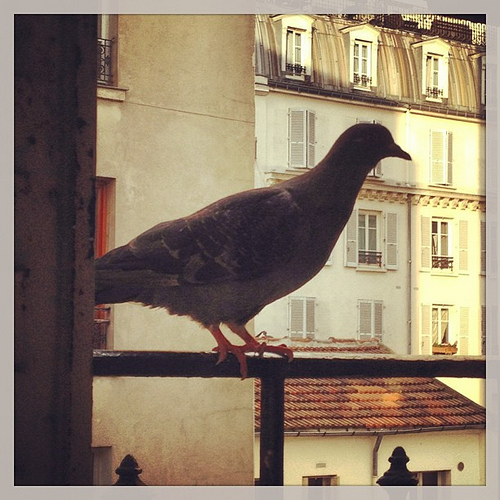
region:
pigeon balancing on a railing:
[83, 117, 421, 390]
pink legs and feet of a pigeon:
[201, 317, 297, 382]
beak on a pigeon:
[390, 144, 418, 166]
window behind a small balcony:
[423, 216, 458, 274]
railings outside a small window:
[347, 70, 382, 93]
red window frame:
[86, 174, 121, 324]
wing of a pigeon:
[104, 185, 314, 291]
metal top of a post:
[372, 442, 419, 485]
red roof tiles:
[252, 374, 484, 441]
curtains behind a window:
[429, 308, 451, 345]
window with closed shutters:
[283, 96, 323, 173]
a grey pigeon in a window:
[104, 112, 412, 337]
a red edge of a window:
[93, 185, 123, 357]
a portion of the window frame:
[17, 19, 129, 499]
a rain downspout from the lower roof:
[364, 430, 394, 496]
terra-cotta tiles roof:
[296, 372, 483, 446]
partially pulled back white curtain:
[425, 281, 467, 352]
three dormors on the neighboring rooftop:
[270, 10, 452, 105]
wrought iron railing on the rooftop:
[371, 17, 493, 51]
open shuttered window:
[332, 191, 407, 278]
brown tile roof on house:
[288, 386, 326, 419]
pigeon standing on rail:
[85, 106, 417, 383]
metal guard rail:
[259, 360, 285, 490]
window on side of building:
[279, 15, 319, 74]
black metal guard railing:
[95, 36, 112, 86]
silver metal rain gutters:
[342, 427, 410, 439]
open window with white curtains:
[425, 293, 462, 360]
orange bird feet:
[198, 319, 299, 379]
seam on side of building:
[128, 92, 253, 127]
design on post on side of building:
[374, 444, 421, 495]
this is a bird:
[85, 110, 411, 360]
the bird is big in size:
[93, 118, 423, 360]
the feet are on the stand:
[191, 330, 298, 374]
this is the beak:
[392, 147, 414, 164]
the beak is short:
[389, 150, 416, 160]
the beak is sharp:
[392, 146, 414, 164]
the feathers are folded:
[179, 217, 262, 274]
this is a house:
[373, 194, 477, 310]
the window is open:
[352, 217, 394, 254]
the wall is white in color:
[448, 285, 467, 300]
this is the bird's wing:
[156, 230, 287, 274]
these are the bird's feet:
[208, 324, 308, 378]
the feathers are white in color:
[201, 292, 258, 315]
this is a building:
[277, 10, 472, 467]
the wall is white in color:
[291, 448, 306, 463]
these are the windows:
[283, 30, 446, 87]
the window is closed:
[353, 44, 375, 97]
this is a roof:
[322, 382, 425, 414]